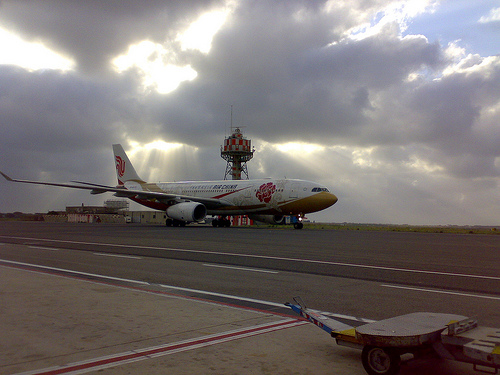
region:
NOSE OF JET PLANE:
[321, 189, 345, 214]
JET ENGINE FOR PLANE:
[166, 200, 211, 225]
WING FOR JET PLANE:
[5, 171, 167, 208]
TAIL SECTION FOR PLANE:
[108, 143, 139, 180]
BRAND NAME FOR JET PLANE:
[252, 175, 282, 207]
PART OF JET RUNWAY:
[325, 235, 390, 264]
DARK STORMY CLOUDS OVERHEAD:
[234, 64, 297, 100]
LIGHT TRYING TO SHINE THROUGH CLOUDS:
[281, 140, 329, 164]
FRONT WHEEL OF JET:
[288, 217, 305, 230]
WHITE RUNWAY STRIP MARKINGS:
[133, 243, 194, 273]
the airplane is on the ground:
[5, 106, 369, 245]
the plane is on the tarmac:
[5, 133, 349, 245]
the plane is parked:
[7, 120, 370, 257]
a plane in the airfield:
[5, 133, 380, 248]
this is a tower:
[213, 105, 272, 217]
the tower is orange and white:
[215, 96, 270, 217]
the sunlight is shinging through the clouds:
[108, 43, 303, 206]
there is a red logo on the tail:
[104, 135, 154, 208]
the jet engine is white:
[158, 188, 223, 226]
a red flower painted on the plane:
[244, 178, 284, 208]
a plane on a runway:
[5, 123, 387, 250]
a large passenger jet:
[10, 135, 387, 276]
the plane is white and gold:
[2, 118, 405, 257]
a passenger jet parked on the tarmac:
[0, 123, 388, 266]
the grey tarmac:
[2, 221, 497, 286]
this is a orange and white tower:
[208, 97, 263, 178]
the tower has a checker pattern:
[220, 86, 273, 198]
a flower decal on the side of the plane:
[245, 179, 295, 224]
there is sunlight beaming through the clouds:
[60, 45, 390, 196]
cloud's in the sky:
[1, 25, 484, 179]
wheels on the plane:
[154, 217, 311, 234]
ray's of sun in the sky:
[109, 132, 196, 187]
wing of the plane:
[0, 182, 221, 204]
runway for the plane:
[3, 229, 489, 312]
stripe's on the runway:
[54, 309, 325, 371]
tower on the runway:
[209, 120, 267, 233]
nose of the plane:
[319, 180, 345, 222]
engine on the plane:
[163, 198, 208, 230]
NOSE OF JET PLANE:
[324, 190, 341, 209]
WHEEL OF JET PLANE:
[290, 214, 309, 229]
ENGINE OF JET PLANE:
[151, 194, 224, 235]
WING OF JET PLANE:
[8, 175, 184, 202]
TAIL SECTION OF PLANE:
[104, 143, 136, 179]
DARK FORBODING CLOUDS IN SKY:
[230, 74, 333, 106]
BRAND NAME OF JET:
[249, 179, 281, 204]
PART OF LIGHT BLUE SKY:
[433, 15, 478, 43]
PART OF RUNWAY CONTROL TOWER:
[216, 123, 259, 177]